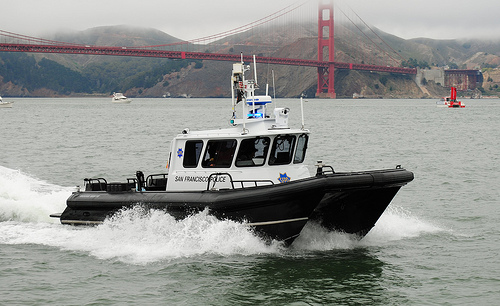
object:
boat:
[51, 52, 414, 248]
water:
[0, 98, 500, 303]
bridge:
[0, 0, 417, 98]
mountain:
[0, 20, 500, 98]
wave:
[0, 168, 447, 265]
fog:
[0, 0, 499, 45]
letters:
[175, 176, 226, 182]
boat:
[436, 87, 465, 108]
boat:
[113, 92, 127, 102]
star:
[278, 173, 291, 183]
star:
[177, 148, 183, 157]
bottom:
[49, 168, 414, 248]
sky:
[0, 0, 499, 46]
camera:
[274, 107, 291, 127]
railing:
[207, 173, 275, 191]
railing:
[84, 178, 107, 191]